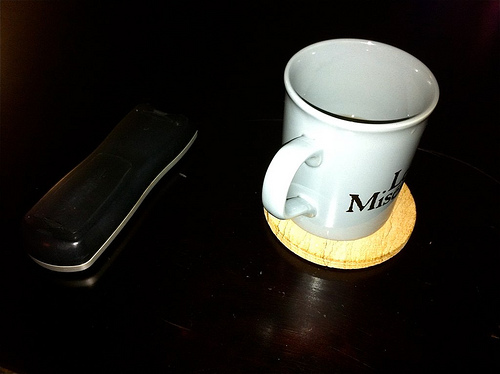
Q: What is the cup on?
A: Coaster.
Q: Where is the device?
A: Table.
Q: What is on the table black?
A: Remote.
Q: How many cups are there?
A: One.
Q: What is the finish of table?
A: Mahogany.